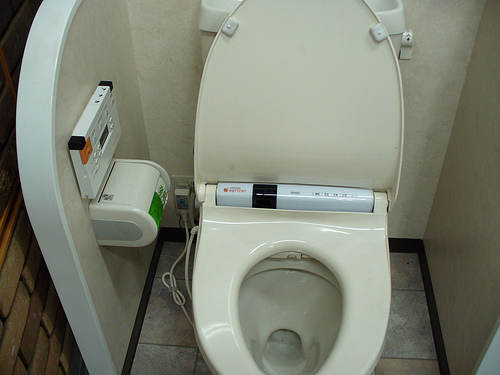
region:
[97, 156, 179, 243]
Toilet paper dispenser hanging on the wall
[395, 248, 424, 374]
Tiled bathroom floor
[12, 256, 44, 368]
Wall made of bricks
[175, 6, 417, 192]
Lid on toilet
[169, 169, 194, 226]
Electrical receptacle behind toilet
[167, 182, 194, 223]
Electrical gadget plugged into receptacle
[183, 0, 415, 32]
Lid to toilet reservoir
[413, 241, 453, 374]
Black baseboard molding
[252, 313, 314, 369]
Drain hole in the bottom of the toilet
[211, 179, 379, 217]
Automatic flusher unit on a toilet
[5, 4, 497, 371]
small bathroom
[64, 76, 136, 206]
a control board on left of toilet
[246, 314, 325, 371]
water in toilet is clean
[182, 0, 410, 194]
lid of bathroom is up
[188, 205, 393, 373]
sit of bathroom is clean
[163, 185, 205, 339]
toilet is connected with a wire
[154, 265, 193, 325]
white wire is coiled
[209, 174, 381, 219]
hinge of toilet has numbers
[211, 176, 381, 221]
hinge of toilet is long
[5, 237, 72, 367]
wall of toilet is made of brick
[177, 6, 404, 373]
cream color toilet with electronics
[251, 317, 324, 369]
dirty gray toilet bowl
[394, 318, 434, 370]
tan and brown stone tile floor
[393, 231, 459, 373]
wooden baseboard around toilet stall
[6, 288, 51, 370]
brown brick wall on left of toilet stall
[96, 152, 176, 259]
tan and green toilet paper dispenser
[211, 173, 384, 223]
electronics on back of toilet below lid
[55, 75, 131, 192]
electronics on wall on left side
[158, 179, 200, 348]
electric cords plugged in to wall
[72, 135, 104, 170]
orange label on toilet electronics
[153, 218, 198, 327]
a white power cord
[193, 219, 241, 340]
a white toilet seat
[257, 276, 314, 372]
the dirty inside of a toilet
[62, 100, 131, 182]
a button pad on the stall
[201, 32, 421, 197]
a white plastic toilet lid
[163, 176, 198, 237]
a cord plugged into the wall outlet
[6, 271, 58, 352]
brown bricks in the wall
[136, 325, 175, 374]
tan and brown tiles on the floor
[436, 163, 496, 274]
a smooth and tan wall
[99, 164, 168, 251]
a white and gray toilet paper dispenser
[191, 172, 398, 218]
temperature hinge on toilet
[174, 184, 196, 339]
cord to plug in thermometer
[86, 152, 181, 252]
toilet paper dispenser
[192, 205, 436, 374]
clean tan toilet seat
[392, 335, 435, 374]
tan and beige floor tile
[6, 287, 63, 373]
multi-colored brick on wall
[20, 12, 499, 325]
tan toilet surround unit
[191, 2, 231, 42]
white toilet tank lid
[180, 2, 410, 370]
clean toilet with lid up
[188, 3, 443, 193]
tan toilet seat lid that is in up position